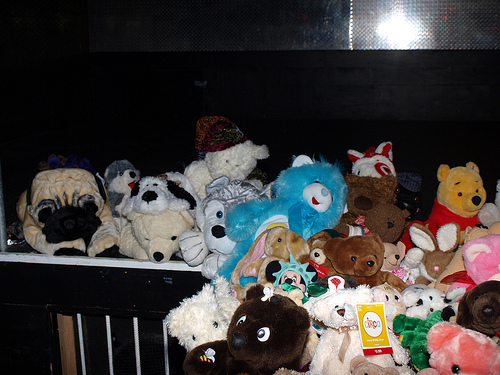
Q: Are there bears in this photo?
A: Yes, there is a bear.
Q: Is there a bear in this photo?
A: Yes, there is a bear.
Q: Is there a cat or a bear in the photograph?
A: Yes, there is a bear.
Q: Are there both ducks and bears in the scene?
A: No, there is a bear but no ducks.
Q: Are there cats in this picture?
A: No, there are no cats.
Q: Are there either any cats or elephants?
A: No, there are no cats or elephants.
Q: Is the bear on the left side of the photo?
A: No, the bear is on the right of the image.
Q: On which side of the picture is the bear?
A: The bear is on the right of the image.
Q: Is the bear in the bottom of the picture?
A: Yes, the bear is in the bottom of the image.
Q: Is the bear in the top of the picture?
A: No, the bear is in the bottom of the image.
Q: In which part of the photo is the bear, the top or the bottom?
A: The bear is in the bottom of the image.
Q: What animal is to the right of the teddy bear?
A: The animal is a bear.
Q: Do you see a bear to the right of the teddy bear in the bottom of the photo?
A: Yes, there is a bear to the right of the teddy bear.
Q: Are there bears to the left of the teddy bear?
A: No, the bear is to the right of the teddy bear.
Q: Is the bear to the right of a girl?
A: No, the bear is to the right of the teddy bear.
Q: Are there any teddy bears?
A: Yes, there is a teddy bear.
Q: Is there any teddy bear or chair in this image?
A: Yes, there is a teddy bear.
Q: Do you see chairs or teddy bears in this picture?
A: Yes, there is a teddy bear.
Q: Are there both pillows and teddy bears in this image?
A: No, there is a teddy bear but no pillows.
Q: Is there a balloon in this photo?
A: No, there are no balloons.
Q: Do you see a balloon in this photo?
A: No, there are no balloons.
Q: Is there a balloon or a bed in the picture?
A: No, there are no balloons or beds.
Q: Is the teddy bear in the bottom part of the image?
A: Yes, the teddy bear is in the bottom of the image.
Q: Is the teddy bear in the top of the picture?
A: No, the teddy bear is in the bottom of the image.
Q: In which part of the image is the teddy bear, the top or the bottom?
A: The teddy bear is in the bottom of the image.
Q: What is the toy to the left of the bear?
A: The toy is a teddy bear.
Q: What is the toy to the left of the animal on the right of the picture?
A: The toy is a teddy bear.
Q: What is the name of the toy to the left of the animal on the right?
A: The toy is a teddy bear.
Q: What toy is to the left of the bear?
A: The toy is a teddy bear.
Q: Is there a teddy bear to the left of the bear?
A: Yes, there is a teddy bear to the left of the bear.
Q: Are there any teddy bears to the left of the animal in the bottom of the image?
A: Yes, there is a teddy bear to the left of the bear.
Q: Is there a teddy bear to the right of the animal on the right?
A: No, the teddy bear is to the left of the bear.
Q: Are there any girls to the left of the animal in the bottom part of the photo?
A: No, there is a teddy bear to the left of the bear.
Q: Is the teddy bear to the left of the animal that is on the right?
A: Yes, the teddy bear is to the left of the bear.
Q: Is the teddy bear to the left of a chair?
A: No, the teddy bear is to the left of the bear.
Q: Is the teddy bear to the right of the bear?
A: No, the teddy bear is to the left of the bear.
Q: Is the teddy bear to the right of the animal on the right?
A: No, the teddy bear is to the left of the bear.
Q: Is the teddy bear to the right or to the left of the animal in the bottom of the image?
A: The teddy bear is to the left of the bear.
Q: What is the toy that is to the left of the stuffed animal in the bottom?
A: The toy is a teddy bear.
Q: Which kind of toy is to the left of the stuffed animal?
A: The toy is a teddy bear.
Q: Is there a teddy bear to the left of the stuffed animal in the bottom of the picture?
A: Yes, there is a teddy bear to the left of the stuffed animal.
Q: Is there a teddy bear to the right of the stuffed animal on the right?
A: No, the teddy bear is to the left of the stuffed animal.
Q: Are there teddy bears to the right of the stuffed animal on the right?
A: No, the teddy bear is to the left of the stuffed animal.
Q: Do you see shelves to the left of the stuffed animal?
A: No, there is a teddy bear to the left of the stuffed animal.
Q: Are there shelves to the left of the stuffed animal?
A: No, there is a teddy bear to the left of the stuffed animal.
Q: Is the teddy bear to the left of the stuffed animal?
A: Yes, the teddy bear is to the left of the stuffed animal.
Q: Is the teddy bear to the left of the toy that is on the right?
A: Yes, the teddy bear is to the left of the stuffed animal.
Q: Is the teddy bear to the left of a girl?
A: No, the teddy bear is to the left of the stuffed animal.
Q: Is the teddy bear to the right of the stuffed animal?
A: No, the teddy bear is to the left of the stuffed animal.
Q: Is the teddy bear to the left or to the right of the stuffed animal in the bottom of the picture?
A: The teddy bear is to the left of the stuffed animal.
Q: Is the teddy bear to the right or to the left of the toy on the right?
A: The teddy bear is to the left of the stuffed animal.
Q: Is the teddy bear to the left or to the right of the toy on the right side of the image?
A: The teddy bear is to the left of the stuffed animal.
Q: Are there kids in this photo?
A: No, there are no kids.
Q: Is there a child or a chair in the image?
A: No, there are no children or chairs.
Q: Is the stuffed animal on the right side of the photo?
A: Yes, the stuffed animal is on the right of the image.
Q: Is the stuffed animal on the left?
A: No, the stuffed animal is on the right of the image.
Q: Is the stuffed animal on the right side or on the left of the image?
A: The stuffed animal is on the right of the image.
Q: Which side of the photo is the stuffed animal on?
A: The stuffed animal is on the right of the image.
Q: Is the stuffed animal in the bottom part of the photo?
A: Yes, the stuffed animal is in the bottom of the image.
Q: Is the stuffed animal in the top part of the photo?
A: No, the stuffed animal is in the bottom of the image.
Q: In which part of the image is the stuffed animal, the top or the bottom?
A: The stuffed animal is in the bottom of the image.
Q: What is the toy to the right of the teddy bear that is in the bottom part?
A: The toy is a stuffed animal.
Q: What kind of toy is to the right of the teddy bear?
A: The toy is a stuffed animal.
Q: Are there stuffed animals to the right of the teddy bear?
A: Yes, there is a stuffed animal to the right of the teddy bear.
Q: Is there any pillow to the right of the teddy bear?
A: No, there is a stuffed animal to the right of the teddy bear.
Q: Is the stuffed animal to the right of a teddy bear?
A: Yes, the stuffed animal is to the right of a teddy bear.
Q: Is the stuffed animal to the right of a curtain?
A: No, the stuffed animal is to the right of a teddy bear.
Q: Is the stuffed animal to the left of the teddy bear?
A: No, the stuffed animal is to the right of the teddy bear.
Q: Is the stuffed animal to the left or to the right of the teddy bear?
A: The stuffed animal is to the right of the teddy bear.